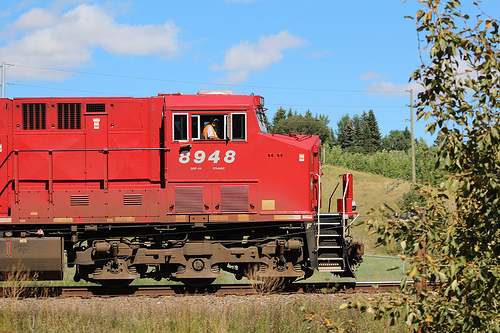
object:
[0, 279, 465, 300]
tracks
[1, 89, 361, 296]
train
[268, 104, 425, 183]
trees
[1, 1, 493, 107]
sky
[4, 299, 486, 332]
grass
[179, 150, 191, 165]
number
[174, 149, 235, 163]
number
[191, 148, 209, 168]
number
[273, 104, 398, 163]
leaves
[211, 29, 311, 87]
clouds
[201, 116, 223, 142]
man